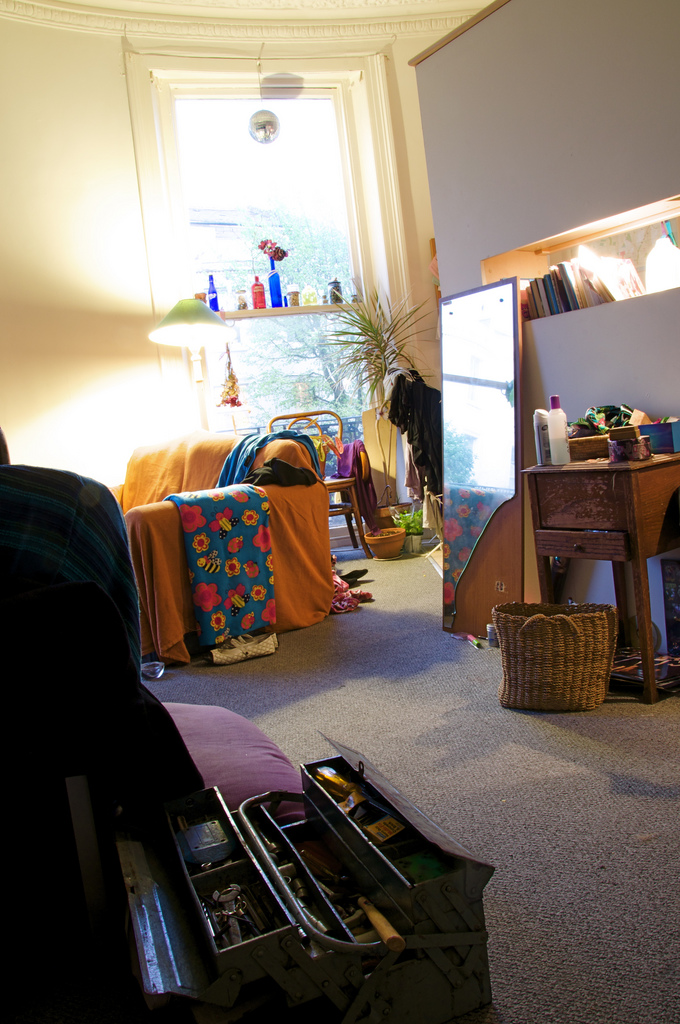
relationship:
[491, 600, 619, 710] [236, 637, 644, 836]
bag on floor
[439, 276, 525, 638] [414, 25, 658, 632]
mirror leaning on a wall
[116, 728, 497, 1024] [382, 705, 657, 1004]
bag sitting on floor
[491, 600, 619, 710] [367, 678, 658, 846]
bag sitting on floor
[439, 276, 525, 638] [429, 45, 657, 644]
mirror leaning on wall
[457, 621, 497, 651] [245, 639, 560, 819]
tube laying on floor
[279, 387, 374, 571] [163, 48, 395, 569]
chair in front of window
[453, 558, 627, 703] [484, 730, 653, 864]
bag on floor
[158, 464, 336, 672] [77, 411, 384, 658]
blanket over chair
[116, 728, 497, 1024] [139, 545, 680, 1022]
bag on carpet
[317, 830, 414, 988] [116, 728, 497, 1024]
hammer in bag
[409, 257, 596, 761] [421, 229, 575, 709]
mirror leaning on wall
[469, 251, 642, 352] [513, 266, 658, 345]
books lined on shelf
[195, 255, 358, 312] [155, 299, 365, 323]
bottles on ledge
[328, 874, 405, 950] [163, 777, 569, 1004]
hammer in toolbox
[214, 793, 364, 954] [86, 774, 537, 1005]
tool in bag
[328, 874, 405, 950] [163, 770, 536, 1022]
hammer in bag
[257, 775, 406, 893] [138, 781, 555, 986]
tool in bag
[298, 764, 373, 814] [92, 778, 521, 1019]
tool in bag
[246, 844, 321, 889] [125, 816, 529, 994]
tool in bag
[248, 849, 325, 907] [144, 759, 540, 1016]
tool in bag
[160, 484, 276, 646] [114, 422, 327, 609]
blanket on chair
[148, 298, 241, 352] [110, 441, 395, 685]
lamp behind chair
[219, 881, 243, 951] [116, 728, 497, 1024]
tool in bag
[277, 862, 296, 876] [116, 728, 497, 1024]
tool in bag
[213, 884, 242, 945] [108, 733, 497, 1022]
tool in bag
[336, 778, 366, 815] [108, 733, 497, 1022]
tool in bag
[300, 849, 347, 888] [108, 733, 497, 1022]
tool in bag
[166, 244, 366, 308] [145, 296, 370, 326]
bottles are on ledge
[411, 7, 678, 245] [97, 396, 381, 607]
white wall behind chair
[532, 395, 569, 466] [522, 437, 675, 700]
bottle sitting on table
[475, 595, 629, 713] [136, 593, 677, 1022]
basket on floor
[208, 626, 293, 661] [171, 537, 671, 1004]
shoe on floor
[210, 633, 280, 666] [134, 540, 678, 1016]
shoe on floor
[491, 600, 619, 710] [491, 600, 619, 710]
bag of bag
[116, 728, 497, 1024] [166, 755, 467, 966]
bag full of tools